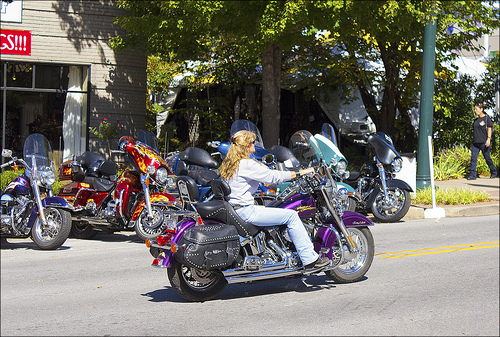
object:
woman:
[463, 101, 500, 178]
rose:
[103, 116, 109, 121]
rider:
[223, 124, 332, 272]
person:
[460, 101, 500, 179]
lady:
[224, 128, 337, 271]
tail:
[220, 145, 235, 173]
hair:
[218, 131, 255, 179]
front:
[307, 145, 365, 201]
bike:
[160, 133, 379, 297]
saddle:
[180, 200, 236, 226]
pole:
[414, 15, 435, 200]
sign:
[0, 28, 33, 61]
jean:
[234, 204, 318, 264]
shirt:
[217, 158, 292, 204]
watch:
[294, 169, 301, 178]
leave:
[303, 39, 318, 51]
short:
[468, 144, 497, 177]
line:
[370, 236, 500, 264]